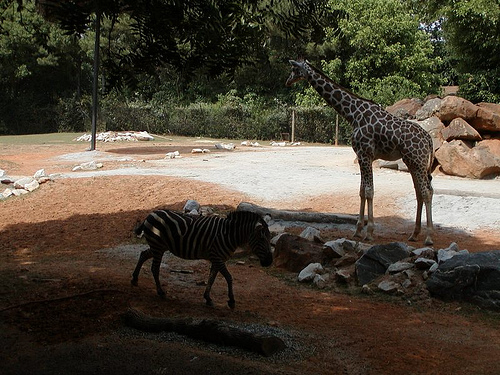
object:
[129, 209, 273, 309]
zebra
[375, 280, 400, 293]
rocks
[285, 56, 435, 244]
giraffe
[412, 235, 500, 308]
rocks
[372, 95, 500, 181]
rocks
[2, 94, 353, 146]
fence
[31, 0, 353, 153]
tree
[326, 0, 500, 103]
tree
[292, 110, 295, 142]
pin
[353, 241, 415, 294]
rocks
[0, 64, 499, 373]
enclosure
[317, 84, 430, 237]
side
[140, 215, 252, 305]
side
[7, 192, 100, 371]
dirt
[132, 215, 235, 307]
torso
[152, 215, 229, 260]
stripes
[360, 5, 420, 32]
leaves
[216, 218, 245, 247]
neck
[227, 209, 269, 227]
mane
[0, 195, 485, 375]
shadow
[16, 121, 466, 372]
ground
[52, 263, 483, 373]
surface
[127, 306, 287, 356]
log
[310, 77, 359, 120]
neck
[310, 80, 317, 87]
spots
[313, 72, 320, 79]
spots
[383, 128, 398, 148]
brown spots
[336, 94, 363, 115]
brown spots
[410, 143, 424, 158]
brown spots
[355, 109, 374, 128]
brown spots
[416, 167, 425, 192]
brown spots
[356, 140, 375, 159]
brown spots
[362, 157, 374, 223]
giraffe leg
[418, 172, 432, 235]
giraffe leg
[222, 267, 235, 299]
zebra leg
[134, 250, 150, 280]
zebra leg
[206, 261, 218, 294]
zebra leg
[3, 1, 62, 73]
green leaves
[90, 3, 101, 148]
vertical pole